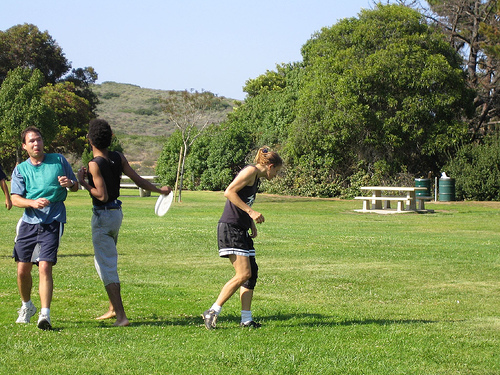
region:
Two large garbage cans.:
[412, 167, 454, 199]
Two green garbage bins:
[415, 170, 455, 201]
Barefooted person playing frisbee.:
[75, 120, 178, 337]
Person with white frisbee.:
[78, 102, 175, 332]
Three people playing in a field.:
[7, 115, 287, 343]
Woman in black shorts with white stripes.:
[207, 134, 283, 337]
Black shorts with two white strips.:
[212, 213, 261, 258]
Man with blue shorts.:
[9, 122, 77, 328]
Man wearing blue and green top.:
[10, 125, 75, 332]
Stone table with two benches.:
[352, 175, 437, 217]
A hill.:
[84, 72, 240, 185]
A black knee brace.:
[241, 258, 258, 286]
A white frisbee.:
[152, 189, 174, 216]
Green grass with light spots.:
[4, 177, 496, 374]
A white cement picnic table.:
[354, 181, 431, 216]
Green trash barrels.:
[414, 173, 456, 204]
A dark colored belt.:
[92, 204, 122, 211]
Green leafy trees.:
[0, 1, 478, 203]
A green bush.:
[440, 140, 498, 203]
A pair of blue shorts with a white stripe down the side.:
[17, 224, 63, 263]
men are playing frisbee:
[10, 108, 380, 345]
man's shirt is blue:
[12, 147, 79, 224]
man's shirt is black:
[224, 164, 266, 223]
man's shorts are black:
[192, 220, 277, 267]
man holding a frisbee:
[117, 161, 199, 228]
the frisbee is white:
[131, 166, 191, 221]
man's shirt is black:
[73, 150, 145, 215]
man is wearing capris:
[70, 204, 145, 277]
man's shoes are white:
[9, 296, 66, 337]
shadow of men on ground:
[142, 274, 414, 350]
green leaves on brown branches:
[336, 22, 415, 53]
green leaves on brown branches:
[305, 83, 363, 115]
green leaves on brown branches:
[363, 58, 405, 112]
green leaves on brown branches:
[406, 82, 456, 128]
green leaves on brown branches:
[435, 110, 467, 143]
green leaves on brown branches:
[254, 81, 318, 121]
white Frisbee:
[149, 179, 184, 229]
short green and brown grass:
[278, 225, 336, 269]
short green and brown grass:
[298, 275, 374, 342]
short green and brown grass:
[142, 326, 212, 359]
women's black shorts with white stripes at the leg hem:
[213, 220, 258, 259]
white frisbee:
[154, 188, 176, 217]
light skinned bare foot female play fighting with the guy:
[76, 113, 169, 331]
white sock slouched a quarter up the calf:
[239, 310, 267, 330]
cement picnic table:
[353, 184, 435, 211]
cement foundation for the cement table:
[348, 207, 443, 215]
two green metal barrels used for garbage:
[412, 176, 457, 204]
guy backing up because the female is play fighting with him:
[8, 126, 75, 331]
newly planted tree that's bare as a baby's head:
[167, 98, 210, 204]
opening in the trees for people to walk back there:
[119, 116, 170, 187]